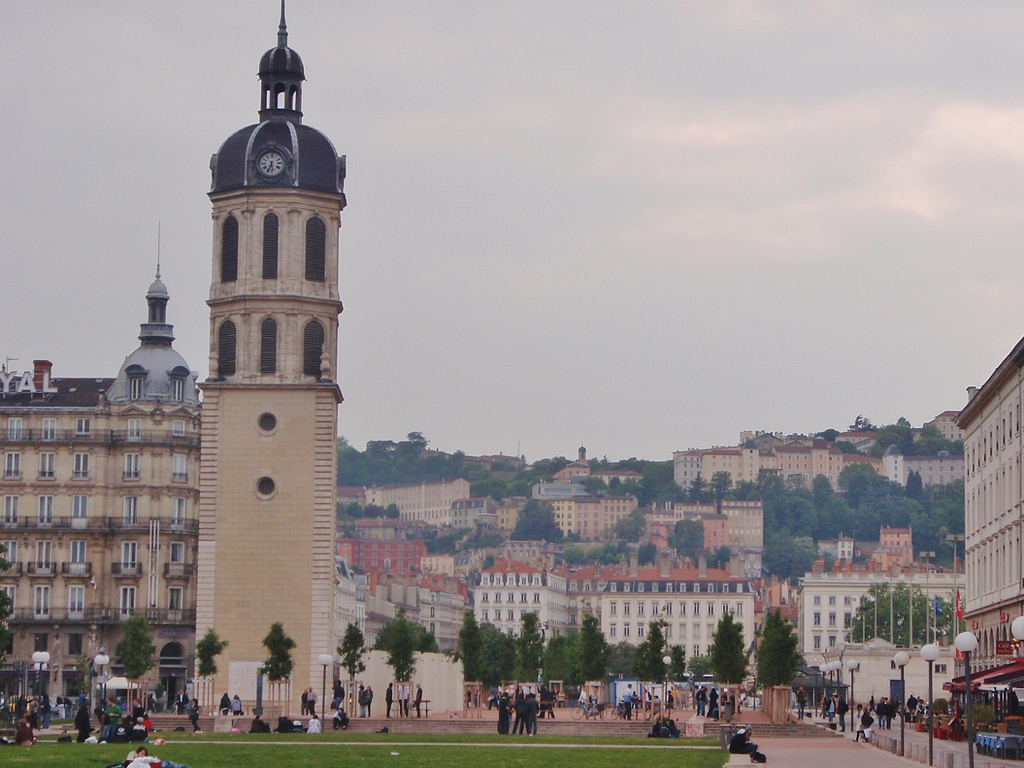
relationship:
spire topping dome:
[277, 1, 290, 45] [256, 40, 309, 82]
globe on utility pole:
[910, 632, 949, 667] [918, 656, 942, 765]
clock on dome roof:
[257, 152, 285, 178] [203, 112, 353, 203]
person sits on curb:
[720, 725, 768, 765] [720, 747, 759, 765]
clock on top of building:
[261, 155, 285, 177] [187, 8, 352, 735]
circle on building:
[256, 408, 278, 428] [187, 8, 352, 735]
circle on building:
[246, 471, 283, 500] [187, 8, 352, 735]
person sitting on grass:
[120, 741, 147, 761] [4, 723, 733, 767]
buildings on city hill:
[669, 434, 966, 487] [334, 411, 963, 719]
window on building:
[120, 541, 129, 552] [0, 351, 215, 648]